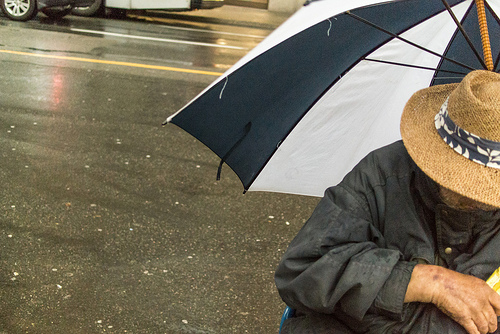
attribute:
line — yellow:
[0, 47, 223, 76]